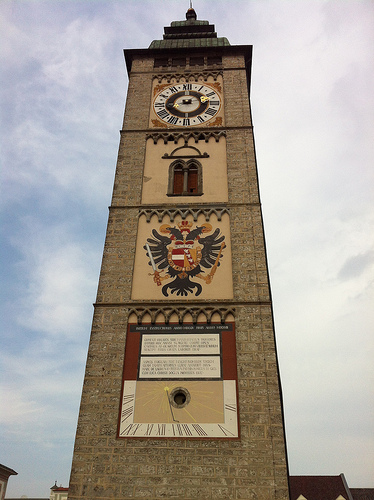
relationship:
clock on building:
[154, 82, 222, 126] [73, 28, 306, 495]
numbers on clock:
[158, 79, 202, 93] [139, 80, 228, 145]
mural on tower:
[120, 196, 250, 305] [85, 29, 262, 477]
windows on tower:
[148, 151, 200, 199] [71, 47, 323, 498]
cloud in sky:
[9, 213, 108, 355] [0, 2, 372, 495]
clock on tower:
[154, 82, 222, 126] [49, 5, 295, 498]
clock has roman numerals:
[154, 82, 222, 126] [151, 75, 220, 130]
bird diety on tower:
[139, 214, 235, 302] [49, 5, 295, 498]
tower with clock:
[49, 5, 295, 498] [150, 75, 220, 128]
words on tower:
[142, 337, 218, 376] [49, 5, 295, 498]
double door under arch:
[165, 157, 208, 192] [162, 138, 209, 162]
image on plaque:
[165, 383, 193, 425] [115, 373, 237, 436]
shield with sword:
[143, 220, 226, 297] [143, 236, 162, 279]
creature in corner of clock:
[203, 115, 223, 128] [150, 75, 220, 128]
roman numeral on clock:
[177, 79, 193, 93] [154, 82, 222, 126]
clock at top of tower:
[154, 82, 222, 126] [49, 5, 295, 498]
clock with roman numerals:
[150, 78, 223, 124] [154, 79, 220, 129]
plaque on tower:
[123, 321, 235, 382] [49, 5, 295, 498]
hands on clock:
[157, 89, 212, 110] [150, 77, 228, 135]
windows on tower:
[166, 159, 204, 197] [65, 0, 291, 499]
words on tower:
[139, 332, 218, 375] [65, 0, 291, 499]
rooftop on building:
[289, 473, 354, 498] [289, 473, 350, 498]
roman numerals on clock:
[154, 83, 219, 125] [154, 82, 222, 126]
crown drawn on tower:
[171, 218, 194, 232] [65, 0, 291, 499]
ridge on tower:
[93, 299, 271, 305] [65, 0, 291, 499]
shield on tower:
[143, 219, 227, 295] [65, 0, 291, 499]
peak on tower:
[183, 1, 197, 20] [65, 0, 291, 499]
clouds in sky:
[263, 41, 365, 311] [0, 2, 372, 495]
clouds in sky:
[256, 0, 372, 477] [0, 2, 372, 495]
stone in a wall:
[84, 364, 113, 376] [65, 53, 291, 497]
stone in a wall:
[84, 379, 103, 389] [65, 53, 291, 497]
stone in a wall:
[76, 409, 107, 419] [65, 53, 291, 497]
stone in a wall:
[78, 399, 109, 411] [65, 53, 291, 497]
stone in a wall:
[78, 399, 105, 414] [65, 53, 291, 497]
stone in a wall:
[76, 424, 103, 436] [65, 53, 291, 497]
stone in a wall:
[72, 446, 95, 454] [65, 53, 291, 497]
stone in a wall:
[78, 401, 109, 411] [65, 53, 291, 497]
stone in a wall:
[76, 434, 94, 443] [67, 303, 290, 498]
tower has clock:
[49, 5, 295, 498] [154, 82, 222, 126]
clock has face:
[154, 82, 222, 126] [153, 84, 218, 124]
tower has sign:
[49, 5, 295, 498] [116, 322, 241, 440]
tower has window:
[49, 5, 295, 498] [169, 160, 201, 194]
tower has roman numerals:
[49, 5, 295, 498] [154, 83, 219, 125]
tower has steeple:
[49, 5, 295, 498] [169, 1, 209, 25]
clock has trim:
[154, 82, 222, 126] [149, 72, 225, 127]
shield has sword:
[143, 220, 226, 297] [144, 242, 161, 286]